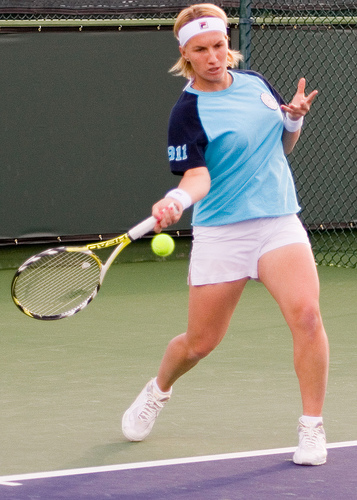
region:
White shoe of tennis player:
[118, 374, 174, 444]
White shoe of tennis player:
[292, 415, 329, 462]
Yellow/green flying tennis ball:
[149, 231, 176, 259]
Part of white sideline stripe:
[38, 454, 195, 468]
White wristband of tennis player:
[167, 188, 199, 205]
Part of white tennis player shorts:
[203, 236, 237, 266]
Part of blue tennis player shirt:
[245, 169, 277, 202]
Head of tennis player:
[164, 4, 250, 82]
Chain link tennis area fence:
[274, 39, 338, 75]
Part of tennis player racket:
[8, 228, 113, 321]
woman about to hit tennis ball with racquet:
[11, 4, 327, 465]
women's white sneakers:
[113, 373, 328, 468]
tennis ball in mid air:
[150, 232, 173, 256]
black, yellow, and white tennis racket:
[8, 193, 181, 321]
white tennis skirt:
[186, 211, 315, 288]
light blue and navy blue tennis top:
[164, 68, 300, 225]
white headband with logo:
[173, 15, 228, 48]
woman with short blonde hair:
[7, 4, 332, 463]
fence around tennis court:
[2, 3, 353, 271]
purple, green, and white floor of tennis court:
[1, 227, 352, 495]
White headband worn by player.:
[174, 13, 228, 49]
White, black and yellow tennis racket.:
[6, 197, 179, 328]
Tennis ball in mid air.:
[147, 224, 176, 259]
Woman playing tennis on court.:
[8, 1, 340, 463]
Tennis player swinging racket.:
[6, 5, 333, 466]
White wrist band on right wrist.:
[164, 183, 190, 208]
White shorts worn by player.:
[181, 205, 325, 286]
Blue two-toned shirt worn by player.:
[161, 63, 301, 218]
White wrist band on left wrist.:
[280, 107, 305, 133]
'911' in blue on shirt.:
[166, 141, 192, 164]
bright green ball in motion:
[147, 228, 176, 258]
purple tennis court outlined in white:
[1, 437, 354, 499]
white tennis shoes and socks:
[107, 381, 341, 463]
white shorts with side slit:
[185, 214, 321, 291]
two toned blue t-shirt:
[166, 75, 302, 220]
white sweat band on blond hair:
[172, 3, 231, 48]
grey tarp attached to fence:
[1, 26, 191, 242]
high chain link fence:
[239, 0, 353, 269]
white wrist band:
[270, 109, 306, 139]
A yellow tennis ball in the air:
[151, 234, 174, 256]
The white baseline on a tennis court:
[180, 455, 207, 463]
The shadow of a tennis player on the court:
[225, 469, 243, 484]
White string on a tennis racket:
[30, 287, 51, 303]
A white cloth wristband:
[290, 121, 300, 130]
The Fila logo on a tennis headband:
[193, 22, 211, 29]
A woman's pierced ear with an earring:
[185, 58, 190, 61]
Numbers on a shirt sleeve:
[167, 142, 187, 161]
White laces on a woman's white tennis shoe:
[298, 420, 322, 451]